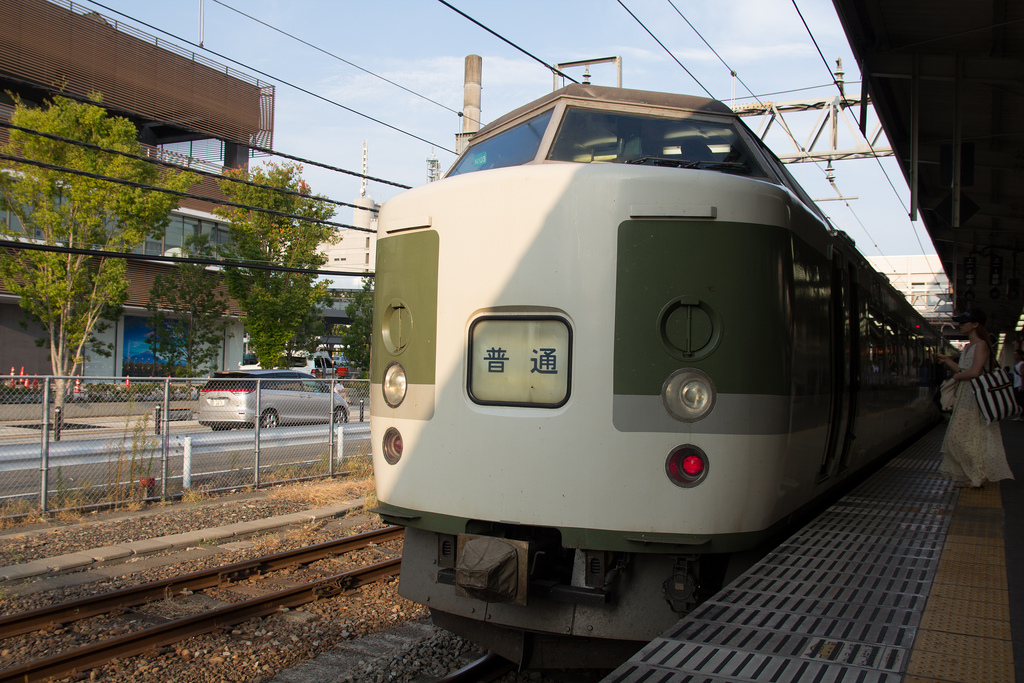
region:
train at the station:
[351, 70, 873, 637]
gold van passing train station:
[155, 342, 470, 555]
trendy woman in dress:
[894, 278, 1022, 535]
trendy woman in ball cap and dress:
[887, 266, 1020, 538]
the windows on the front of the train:
[465, 110, 728, 191]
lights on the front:
[367, 338, 737, 491]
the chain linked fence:
[36, 362, 449, 492]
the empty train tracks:
[38, 523, 514, 680]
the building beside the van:
[22, 44, 285, 393]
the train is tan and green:
[326, 55, 966, 659]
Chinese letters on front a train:
[467, 322, 567, 389]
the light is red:
[662, 435, 710, 494]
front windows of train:
[442, 77, 743, 204]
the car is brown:
[186, 349, 358, 441]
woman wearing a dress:
[922, 289, 1022, 489]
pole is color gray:
[166, 428, 208, 502]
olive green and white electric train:
[364, 91, 966, 627]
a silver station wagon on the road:
[189, 369, 355, 437]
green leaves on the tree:
[49, 212, 215, 355]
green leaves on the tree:
[207, 256, 245, 285]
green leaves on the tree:
[216, 271, 251, 352]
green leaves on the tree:
[254, 276, 265, 296]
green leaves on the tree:
[269, 221, 330, 323]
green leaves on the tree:
[128, 156, 183, 229]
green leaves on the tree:
[38, 180, 155, 367]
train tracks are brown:
[61, 505, 438, 680]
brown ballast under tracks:
[70, 566, 298, 680]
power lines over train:
[225, 1, 892, 118]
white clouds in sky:
[304, 4, 461, 232]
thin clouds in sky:
[292, 37, 520, 127]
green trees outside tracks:
[20, 86, 309, 501]